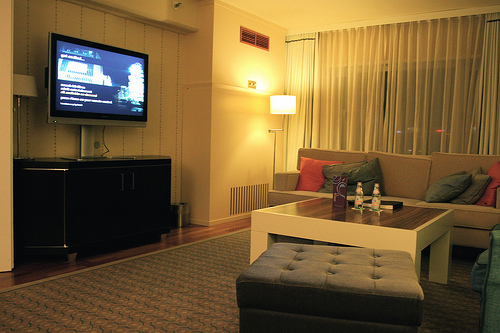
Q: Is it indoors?
A: Yes, it is indoors.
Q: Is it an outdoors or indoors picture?
A: It is indoors.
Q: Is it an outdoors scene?
A: No, it is indoors.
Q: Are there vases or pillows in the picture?
A: Yes, there are pillows.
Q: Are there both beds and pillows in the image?
A: No, there are pillows but no beds.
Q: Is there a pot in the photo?
A: No, there are no pots.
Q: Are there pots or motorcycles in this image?
A: No, there are no pots or motorcycles.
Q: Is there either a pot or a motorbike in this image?
A: No, there are no pots or motorcycles.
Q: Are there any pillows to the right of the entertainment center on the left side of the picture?
A: Yes, there are pillows to the right of the entertainment center.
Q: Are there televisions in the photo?
A: Yes, there is a television.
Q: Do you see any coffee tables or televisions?
A: Yes, there is a television.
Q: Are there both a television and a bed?
A: No, there is a television but no beds.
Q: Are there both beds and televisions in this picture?
A: No, there is a television but no beds.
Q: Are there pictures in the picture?
A: No, there are no pictures.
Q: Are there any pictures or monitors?
A: No, there are no pictures or monitors.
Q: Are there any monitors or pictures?
A: No, there are no pictures or monitors.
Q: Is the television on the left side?
A: Yes, the television is on the left of the image.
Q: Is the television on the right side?
A: No, the television is on the left of the image.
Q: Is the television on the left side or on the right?
A: The television is on the left of the image.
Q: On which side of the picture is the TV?
A: The TV is on the left of the image.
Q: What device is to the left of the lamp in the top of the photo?
A: The device is a television.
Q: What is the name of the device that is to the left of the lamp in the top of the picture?
A: The device is a television.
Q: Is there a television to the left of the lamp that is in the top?
A: Yes, there is a television to the left of the lamp.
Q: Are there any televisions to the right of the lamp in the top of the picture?
A: No, the television is to the left of the lamp.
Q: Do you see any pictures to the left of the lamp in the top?
A: No, there is a television to the left of the lamp.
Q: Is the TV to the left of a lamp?
A: Yes, the TV is to the left of a lamp.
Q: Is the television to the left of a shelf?
A: No, the television is to the left of a lamp.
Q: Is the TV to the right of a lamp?
A: No, the TV is to the left of a lamp.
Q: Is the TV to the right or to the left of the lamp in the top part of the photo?
A: The TV is to the left of the lamp.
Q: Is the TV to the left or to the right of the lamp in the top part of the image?
A: The TV is to the left of the lamp.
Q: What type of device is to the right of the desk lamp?
A: The device is a television.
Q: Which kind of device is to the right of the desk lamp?
A: The device is a television.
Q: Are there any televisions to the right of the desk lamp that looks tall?
A: Yes, there is a television to the right of the desk lamp.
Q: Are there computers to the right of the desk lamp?
A: No, there is a television to the right of the desk lamp.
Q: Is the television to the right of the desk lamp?
A: Yes, the television is to the right of the desk lamp.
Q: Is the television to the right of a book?
A: No, the television is to the right of the desk lamp.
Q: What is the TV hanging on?
A: The TV is hanging on the wall.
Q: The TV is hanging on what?
A: The TV is hanging on the wall.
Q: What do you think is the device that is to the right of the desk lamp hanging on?
A: The TV is hanging on the wall.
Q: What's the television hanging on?
A: The TV is hanging on the wall.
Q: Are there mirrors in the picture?
A: No, there are no mirrors.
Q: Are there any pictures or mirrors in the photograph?
A: No, there are no mirrors or pictures.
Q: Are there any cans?
A: No, there are no cans.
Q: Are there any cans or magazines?
A: No, there are no cans or magazines.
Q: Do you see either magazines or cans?
A: No, there are no cans or magazines.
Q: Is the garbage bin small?
A: Yes, the garbage bin is small.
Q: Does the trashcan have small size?
A: Yes, the trashcan is small.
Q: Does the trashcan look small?
A: Yes, the trashcan is small.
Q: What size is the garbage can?
A: The garbage can is small.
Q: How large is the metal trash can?
A: The trash can is small.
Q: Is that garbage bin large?
A: No, the garbage bin is small.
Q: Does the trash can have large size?
A: No, the trash can is small.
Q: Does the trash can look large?
A: No, the trash can is small.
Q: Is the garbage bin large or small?
A: The garbage bin is small.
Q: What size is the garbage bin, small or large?
A: The garbage bin is small.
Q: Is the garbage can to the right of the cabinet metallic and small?
A: Yes, the garbage bin is metallic and small.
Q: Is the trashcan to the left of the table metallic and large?
A: No, the garbage bin is metallic but small.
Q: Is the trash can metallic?
A: Yes, the trash can is metallic.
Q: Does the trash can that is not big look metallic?
A: Yes, the trash can is metallic.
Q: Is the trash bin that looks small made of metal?
A: Yes, the trashcan is made of metal.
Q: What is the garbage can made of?
A: The garbage can is made of metal.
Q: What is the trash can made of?
A: The garbage can is made of metal.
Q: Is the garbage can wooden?
A: No, the garbage can is metallic.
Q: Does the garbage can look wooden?
A: No, the garbage can is metallic.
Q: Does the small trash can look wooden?
A: No, the trash can is metallic.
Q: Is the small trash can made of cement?
A: No, the garbage bin is made of metal.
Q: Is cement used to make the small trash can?
A: No, the garbage bin is made of metal.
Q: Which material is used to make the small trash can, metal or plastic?
A: The trash bin is made of metal.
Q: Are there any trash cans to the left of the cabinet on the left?
A: No, the trash can is to the right of the cabinet.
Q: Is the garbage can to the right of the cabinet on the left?
A: Yes, the garbage can is to the right of the cabinet.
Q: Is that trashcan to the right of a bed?
A: No, the trashcan is to the right of the cabinet.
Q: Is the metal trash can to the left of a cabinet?
A: No, the garbage can is to the right of a cabinet.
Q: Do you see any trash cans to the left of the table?
A: Yes, there is a trash can to the left of the table.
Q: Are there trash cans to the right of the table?
A: No, the trash can is to the left of the table.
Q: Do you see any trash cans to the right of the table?
A: No, the trash can is to the left of the table.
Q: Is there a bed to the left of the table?
A: No, there is a trash can to the left of the table.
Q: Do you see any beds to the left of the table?
A: No, there is a trash can to the left of the table.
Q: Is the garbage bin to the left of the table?
A: Yes, the garbage bin is to the left of the table.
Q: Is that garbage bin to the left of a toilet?
A: No, the garbage bin is to the left of the table.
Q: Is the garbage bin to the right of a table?
A: No, the garbage bin is to the left of a table.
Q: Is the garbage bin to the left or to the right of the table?
A: The garbage bin is to the left of the table.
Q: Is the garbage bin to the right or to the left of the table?
A: The garbage bin is to the left of the table.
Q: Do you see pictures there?
A: No, there are no pictures.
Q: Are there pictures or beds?
A: No, there are no pictures or beds.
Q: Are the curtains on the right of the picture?
A: Yes, the curtains are on the right of the image.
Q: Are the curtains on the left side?
A: No, the curtains are on the right of the image.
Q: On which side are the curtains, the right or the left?
A: The curtains are on the right of the image.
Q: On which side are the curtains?
A: The curtains are on the right of the image.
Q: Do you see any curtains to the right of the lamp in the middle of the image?
A: Yes, there are curtains to the right of the lamp.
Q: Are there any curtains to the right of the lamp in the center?
A: Yes, there are curtains to the right of the lamp.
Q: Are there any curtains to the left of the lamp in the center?
A: No, the curtains are to the right of the lamp.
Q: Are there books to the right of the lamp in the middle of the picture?
A: No, there are curtains to the right of the lamp.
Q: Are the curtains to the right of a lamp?
A: Yes, the curtains are to the right of a lamp.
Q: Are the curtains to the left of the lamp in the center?
A: No, the curtains are to the right of the lamp.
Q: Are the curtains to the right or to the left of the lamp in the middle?
A: The curtains are to the right of the lamp.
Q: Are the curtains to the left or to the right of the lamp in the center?
A: The curtains are to the right of the lamp.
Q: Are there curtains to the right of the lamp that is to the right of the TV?
A: Yes, there are curtains to the right of the lamp.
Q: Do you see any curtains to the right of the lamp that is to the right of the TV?
A: Yes, there are curtains to the right of the lamp.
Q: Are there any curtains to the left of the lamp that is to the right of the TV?
A: No, the curtains are to the right of the lamp.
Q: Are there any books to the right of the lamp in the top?
A: No, there are curtains to the right of the lamp.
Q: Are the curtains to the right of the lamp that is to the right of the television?
A: Yes, the curtains are to the right of the lamp.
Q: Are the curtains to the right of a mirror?
A: No, the curtains are to the right of the lamp.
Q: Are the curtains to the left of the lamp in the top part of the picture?
A: No, the curtains are to the right of the lamp.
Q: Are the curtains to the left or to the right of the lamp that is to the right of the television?
A: The curtains are to the right of the lamp.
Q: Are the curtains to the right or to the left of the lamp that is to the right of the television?
A: The curtains are to the right of the lamp.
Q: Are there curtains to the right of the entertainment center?
A: Yes, there are curtains to the right of the entertainment center.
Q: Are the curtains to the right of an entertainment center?
A: Yes, the curtains are to the right of an entertainment center.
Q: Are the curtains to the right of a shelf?
A: No, the curtains are to the right of an entertainment center.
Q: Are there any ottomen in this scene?
A: Yes, there is an ottoman.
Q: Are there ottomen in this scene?
A: Yes, there is an ottoman.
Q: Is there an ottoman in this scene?
A: Yes, there is an ottoman.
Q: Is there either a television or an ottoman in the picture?
A: Yes, there is an ottoman.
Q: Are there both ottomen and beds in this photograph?
A: No, there is an ottoman but no beds.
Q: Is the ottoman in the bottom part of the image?
A: Yes, the ottoman is in the bottom of the image.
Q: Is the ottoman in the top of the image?
A: No, the ottoman is in the bottom of the image.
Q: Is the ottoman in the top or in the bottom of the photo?
A: The ottoman is in the bottom of the image.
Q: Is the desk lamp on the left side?
A: Yes, the desk lamp is on the left of the image.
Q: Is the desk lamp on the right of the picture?
A: No, the desk lamp is on the left of the image.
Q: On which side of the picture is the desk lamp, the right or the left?
A: The desk lamp is on the left of the image.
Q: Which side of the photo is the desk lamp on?
A: The desk lamp is on the left of the image.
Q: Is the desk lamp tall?
A: Yes, the desk lamp is tall.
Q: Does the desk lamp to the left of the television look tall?
A: Yes, the desk lamp is tall.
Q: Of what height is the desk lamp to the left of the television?
A: The desk lamp is tall.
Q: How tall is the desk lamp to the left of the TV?
A: The desk lamp is tall.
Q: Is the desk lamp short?
A: No, the desk lamp is tall.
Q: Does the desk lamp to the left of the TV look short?
A: No, the desk lamp is tall.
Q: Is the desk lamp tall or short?
A: The desk lamp is tall.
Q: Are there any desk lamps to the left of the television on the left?
A: Yes, there is a desk lamp to the left of the TV.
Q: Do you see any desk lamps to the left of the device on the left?
A: Yes, there is a desk lamp to the left of the TV.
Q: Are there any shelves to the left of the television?
A: No, there is a desk lamp to the left of the television.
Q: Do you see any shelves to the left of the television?
A: No, there is a desk lamp to the left of the television.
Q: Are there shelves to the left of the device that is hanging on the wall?
A: No, there is a desk lamp to the left of the television.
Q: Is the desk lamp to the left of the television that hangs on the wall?
A: Yes, the desk lamp is to the left of the TV.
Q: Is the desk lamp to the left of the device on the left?
A: Yes, the desk lamp is to the left of the TV.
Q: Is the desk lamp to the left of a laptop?
A: No, the desk lamp is to the left of the TV.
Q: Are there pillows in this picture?
A: Yes, there is a pillow.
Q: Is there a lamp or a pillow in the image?
A: Yes, there is a pillow.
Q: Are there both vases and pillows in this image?
A: No, there is a pillow but no vases.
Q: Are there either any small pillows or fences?
A: Yes, there is a small pillow.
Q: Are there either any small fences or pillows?
A: Yes, there is a small pillow.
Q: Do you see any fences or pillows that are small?
A: Yes, the pillow is small.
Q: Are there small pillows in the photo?
A: Yes, there is a small pillow.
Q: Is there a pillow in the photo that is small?
A: Yes, there is a small pillow.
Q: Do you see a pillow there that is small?
A: Yes, there is a pillow that is small.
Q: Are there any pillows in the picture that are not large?
A: Yes, there is a small pillow.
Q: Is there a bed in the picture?
A: No, there are no beds.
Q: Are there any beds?
A: No, there are no beds.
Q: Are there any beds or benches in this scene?
A: No, there are no beds or benches.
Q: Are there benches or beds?
A: No, there are no beds or benches.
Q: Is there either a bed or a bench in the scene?
A: No, there are no beds or benches.